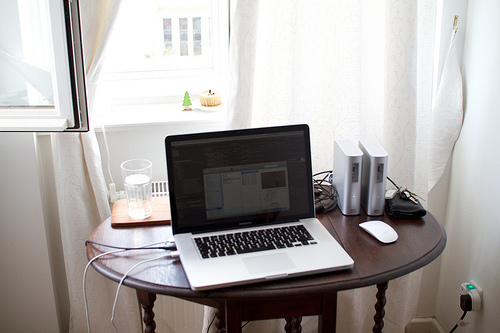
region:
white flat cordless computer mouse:
[358, 220, 396, 243]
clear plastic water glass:
[121, 158, 152, 218]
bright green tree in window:
[181, 91, 190, 108]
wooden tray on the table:
[111, 197, 169, 227]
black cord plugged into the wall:
[448, 295, 470, 330]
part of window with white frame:
[1, 0, 89, 130]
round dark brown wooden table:
[84, 184, 446, 329]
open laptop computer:
[164, 122, 354, 289]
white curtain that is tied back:
[50, 1, 141, 328]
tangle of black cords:
[313, 169, 338, 214]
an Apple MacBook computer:
[161, 126, 353, 296]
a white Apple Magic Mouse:
[358, 217, 399, 245]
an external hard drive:
[332, 134, 362, 216]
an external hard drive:
[357, 134, 386, 217]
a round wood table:
[86, 170, 446, 329]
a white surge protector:
[456, 278, 481, 315]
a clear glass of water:
[118, 158, 152, 221]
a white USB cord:
[109, 248, 177, 330]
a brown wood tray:
[112, 195, 169, 227]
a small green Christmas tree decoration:
[181, 88, 192, 112]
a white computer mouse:
[356, 215, 399, 245]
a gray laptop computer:
[160, 120, 355, 290]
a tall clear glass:
[117, 155, 152, 220]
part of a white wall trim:
[407, 315, 433, 330]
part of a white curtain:
[45, 0, 127, 330]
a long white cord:
[50, 230, 170, 327]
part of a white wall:
[442, 1, 497, 281]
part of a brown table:
[88, 184, 450, 331]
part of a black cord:
[83, 233, 171, 250]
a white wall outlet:
[462, 279, 489, 319]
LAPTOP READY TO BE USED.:
[160, 122, 362, 294]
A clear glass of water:
[110, 148, 160, 225]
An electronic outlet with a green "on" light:
[454, 272, 491, 324]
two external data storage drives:
[322, 124, 402, 223]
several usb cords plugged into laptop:
[70, 233, 200, 322]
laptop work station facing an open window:
[70, 114, 473, 311]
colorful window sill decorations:
[163, 72, 238, 117]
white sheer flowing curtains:
[215, 1, 497, 116]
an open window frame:
[3, 17, 97, 131]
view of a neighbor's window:
[122, 3, 271, 85]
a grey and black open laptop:
[165, 121, 349, 286]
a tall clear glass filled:
[121, 155, 152, 222]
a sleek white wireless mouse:
[365, 219, 395, 246]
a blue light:
[463, 280, 477, 290]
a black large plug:
[441, 291, 471, 324]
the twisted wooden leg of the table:
[140, 286, 157, 330]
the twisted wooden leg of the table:
[213, 306, 225, 329]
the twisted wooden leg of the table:
[280, 302, 300, 331]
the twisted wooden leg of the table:
[372, 275, 392, 330]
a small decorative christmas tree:
[182, 90, 194, 111]